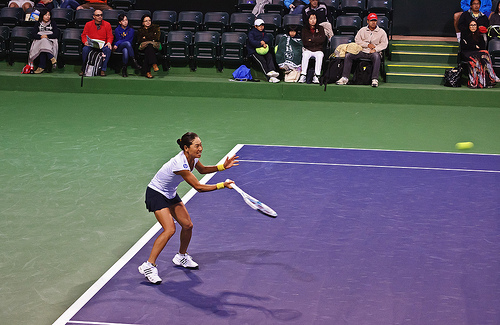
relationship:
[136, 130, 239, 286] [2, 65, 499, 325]
player on court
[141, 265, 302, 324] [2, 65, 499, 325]
shadow on court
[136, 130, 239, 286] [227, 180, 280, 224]
player holding racket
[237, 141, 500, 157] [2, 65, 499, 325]
lines on court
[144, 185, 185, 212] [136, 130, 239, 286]
skirt on player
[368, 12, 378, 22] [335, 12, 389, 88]
cap on person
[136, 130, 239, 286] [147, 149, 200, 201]
player wearing jersey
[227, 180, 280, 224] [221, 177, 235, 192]
racket in hand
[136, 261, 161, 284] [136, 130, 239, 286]
shoes on player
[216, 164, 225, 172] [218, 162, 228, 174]
bands on wrists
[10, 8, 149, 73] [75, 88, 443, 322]
people watching match